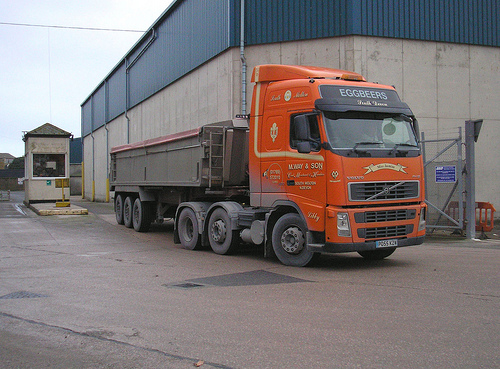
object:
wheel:
[272, 213, 321, 267]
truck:
[106, 64, 426, 267]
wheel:
[358, 246, 397, 259]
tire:
[115, 195, 123, 224]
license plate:
[375, 239, 398, 249]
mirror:
[294, 114, 309, 139]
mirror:
[297, 141, 311, 153]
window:
[289, 111, 321, 152]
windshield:
[322, 111, 420, 148]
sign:
[435, 165, 455, 182]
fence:
[418, 127, 462, 229]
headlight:
[337, 212, 351, 237]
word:
[339, 88, 388, 100]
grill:
[347, 180, 420, 202]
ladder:
[209, 128, 226, 188]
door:
[284, 109, 326, 232]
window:
[33, 154, 66, 177]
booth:
[22, 123, 72, 203]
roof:
[24, 121, 71, 138]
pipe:
[239, 0, 247, 120]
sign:
[55, 178, 70, 188]